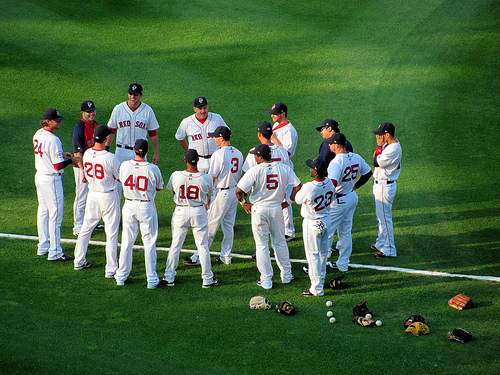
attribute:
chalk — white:
[5, 228, 484, 290]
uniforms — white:
[34, 137, 217, 276]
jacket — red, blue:
[74, 121, 97, 153]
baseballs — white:
[324, 299, 336, 324]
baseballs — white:
[323, 298, 335, 328]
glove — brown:
[449, 292, 472, 311]